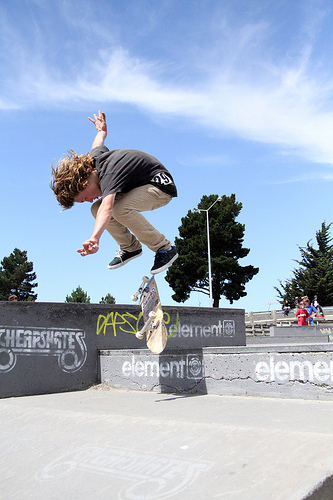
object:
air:
[1, 0, 332, 301]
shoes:
[108, 249, 143, 270]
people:
[282, 295, 324, 324]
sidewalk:
[270, 327, 332, 337]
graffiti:
[96, 311, 179, 338]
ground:
[0, 385, 333, 500]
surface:
[1, 384, 332, 499]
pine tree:
[165, 193, 260, 309]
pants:
[91, 184, 172, 253]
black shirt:
[90, 145, 177, 201]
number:
[154, 173, 169, 186]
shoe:
[150, 246, 178, 274]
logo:
[123, 354, 203, 379]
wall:
[0, 301, 333, 397]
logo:
[169, 320, 235, 338]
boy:
[51, 109, 178, 275]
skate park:
[0, 305, 333, 500]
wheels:
[148, 311, 156, 319]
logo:
[0, 326, 88, 374]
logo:
[255, 359, 333, 383]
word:
[122, 356, 185, 378]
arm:
[91, 131, 107, 152]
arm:
[91, 192, 117, 239]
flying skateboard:
[140, 275, 168, 354]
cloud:
[0, 0, 333, 182]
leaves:
[214, 212, 240, 271]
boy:
[296, 301, 311, 326]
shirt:
[295, 308, 310, 326]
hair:
[49, 149, 92, 214]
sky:
[0, 0, 333, 310]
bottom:
[131, 275, 156, 340]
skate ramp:
[0, 391, 333, 500]